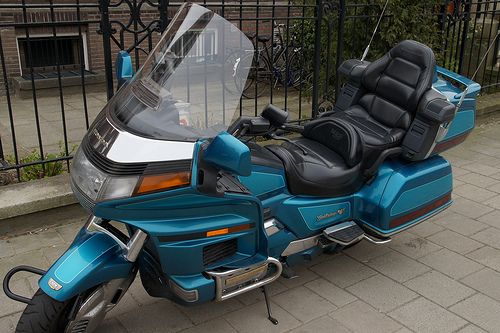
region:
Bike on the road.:
[28, 13, 490, 332]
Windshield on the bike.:
[52, 0, 299, 163]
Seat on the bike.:
[281, 17, 471, 254]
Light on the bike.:
[61, 94, 161, 221]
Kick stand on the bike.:
[238, 264, 343, 331]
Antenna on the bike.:
[349, 19, 498, 123]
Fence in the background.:
[20, 7, 209, 239]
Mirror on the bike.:
[161, 94, 280, 206]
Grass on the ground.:
[16, 115, 123, 216]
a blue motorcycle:
[26, 16, 463, 305]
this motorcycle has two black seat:
[270, 47, 459, 202]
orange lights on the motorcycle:
[122, 164, 202, 214]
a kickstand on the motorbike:
[207, 251, 309, 332]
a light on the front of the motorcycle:
[55, 109, 142, 216]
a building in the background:
[12, 20, 150, 89]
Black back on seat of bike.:
[376, 60, 398, 95]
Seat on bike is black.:
[346, 109, 383, 139]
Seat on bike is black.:
[286, 133, 341, 183]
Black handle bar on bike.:
[230, 110, 307, 141]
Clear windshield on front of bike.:
[148, 38, 223, 110]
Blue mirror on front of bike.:
[210, 134, 258, 183]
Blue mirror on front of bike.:
[108, 48, 147, 88]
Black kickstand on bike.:
[256, 278, 273, 318]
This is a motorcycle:
[55, 16, 475, 331]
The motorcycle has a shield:
[93, 0, 271, 152]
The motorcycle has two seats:
[261, 21, 455, 197]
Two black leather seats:
[237, 26, 447, 210]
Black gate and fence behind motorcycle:
[5, 0, 497, 187]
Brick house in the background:
[5, 1, 497, 98]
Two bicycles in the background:
[220, 15, 314, 102]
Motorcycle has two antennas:
[317, 0, 499, 90]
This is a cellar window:
[12, 20, 114, 97]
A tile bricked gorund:
[352, 270, 474, 330]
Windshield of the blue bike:
[132, 3, 237, 133]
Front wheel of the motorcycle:
[37, 226, 116, 328]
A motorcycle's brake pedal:
[258, 282, 280, 327]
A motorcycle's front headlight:
[69, 143, 136, 202]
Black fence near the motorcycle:
[8, 12, 85, 114]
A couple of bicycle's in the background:
[254, 24, 303, 86]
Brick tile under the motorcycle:
[331, 268, 431, 321]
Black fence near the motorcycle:
[20, 19, 85, 119]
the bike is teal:
[11, 10, 495, 330]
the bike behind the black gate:
[234, 22, 308, 97]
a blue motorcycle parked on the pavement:
[3, 1, 480, 331]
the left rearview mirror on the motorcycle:
[201, 130, 253, 177]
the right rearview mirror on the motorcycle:
[113, 48, 133, 80]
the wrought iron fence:
[1, 0, 499, 181]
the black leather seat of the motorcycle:
[265, 38, 437, 197]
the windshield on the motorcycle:
[106, 0, 255, 140]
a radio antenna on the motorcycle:
[441, 22, 497, 127]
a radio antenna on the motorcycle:
[360, 0, 388, 60]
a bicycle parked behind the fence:
[233, 24, 310, 98]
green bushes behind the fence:
[293, 0, 483, 117]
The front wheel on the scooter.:
[10, 243, 103, 325]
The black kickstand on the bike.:
[258, 278, 279, 320]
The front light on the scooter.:
[66, 148, 133, 204]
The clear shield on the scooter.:
[102, 1, 256, 145]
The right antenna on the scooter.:
[441, 10, 498, 95]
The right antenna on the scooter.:
[357, 1, 379, 64]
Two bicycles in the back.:
[220, 25, 314, 95]